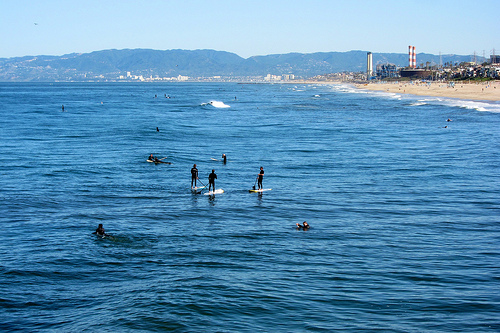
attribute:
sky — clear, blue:
[1, 0, 491, 59]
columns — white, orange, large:
[406, 46, 421, 78]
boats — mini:
[180, 178, 271, 202]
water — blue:
[10, 83, 494, 325]